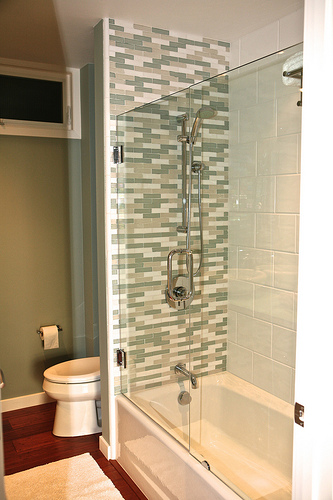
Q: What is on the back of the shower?
A: Tiles.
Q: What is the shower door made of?
A: Glass.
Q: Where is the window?
A: Above the toilet.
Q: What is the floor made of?
A: Wood.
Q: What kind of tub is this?
A: White.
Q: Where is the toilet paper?
A: On a roll.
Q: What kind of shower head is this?
A: Metal.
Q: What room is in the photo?
A: Bathroom.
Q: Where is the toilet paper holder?
A: The wall.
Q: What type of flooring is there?
A: Wood.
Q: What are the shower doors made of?
A: Glass.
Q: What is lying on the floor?
A: Rug.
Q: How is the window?
A: Closed.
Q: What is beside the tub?
A: A rug.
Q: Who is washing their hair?
A: No one.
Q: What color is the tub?
A: White.